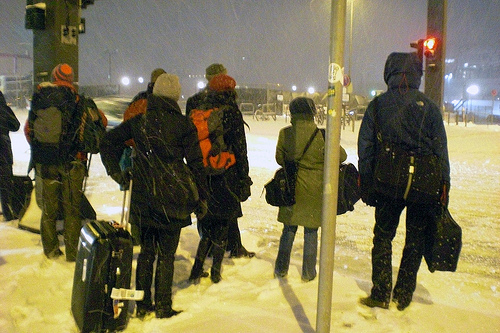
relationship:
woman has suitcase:
[107, 69, 217, 325] [64, 166, 144, 333]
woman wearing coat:
[107, 69, 217, 325] [93, 91, 204, 233]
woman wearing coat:
[248, 87, 359, 294] [259, 116, 349, 235]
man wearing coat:
[339, 47, 458, 315] [348, 47, 464, 214]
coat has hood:
[348, 47, 464, 214] [374, 53, 429, 92]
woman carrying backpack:
[168, 74, 260, 287] [178, 98, 242, 180]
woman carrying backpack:
[248, 87, 359, 294] [316, 149, 374, 225]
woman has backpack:
[248, 87, 359, 294] [316, 149, 374, 225]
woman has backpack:
[168, 74, 260, 287] [178, 98, 242, 180]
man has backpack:
[9, 54, 115, 273] [60, 90, 111, 160]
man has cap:
[9, 54, 115, 273] [45, 57, 79, 90]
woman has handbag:
[107, 69, 217, 325] [139, 109, 211, 226]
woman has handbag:
[248, 87, 359, 294] [256, 155, 304, 213]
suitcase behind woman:
[64, 166, 144, 333] [107, 69, 217, 325]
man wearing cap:
[9, 54, 115, 273] [45, 57, 79, 90]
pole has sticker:
[308, 1, 356, 331] [323, 59, 345, 85]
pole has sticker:
[308, 1, 356, 331] [322, 83, 341, 106]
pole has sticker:
[308, 1, 356, 331] [323, 106, 339, 120]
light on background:
[117, 75, 132, 90] [64, 64, 196, 89]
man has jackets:
[350, 41, 455, 315] [45, 34, 457, 283]